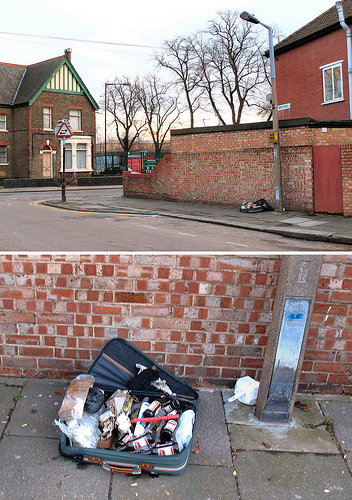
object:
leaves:
[93, 202, 126, 208]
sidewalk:
[43, 197, 352, 252]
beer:
[160, 410, 182, 445]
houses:
[0, 47, 170, 189]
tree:
[99, 76, 145, 171]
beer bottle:
[144, 397, 167, 427]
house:
[262, 0, 352, 120]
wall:
[123, 117, 352, 218]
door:
[56, 123, 73, 137]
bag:
[228, 376, 261, 405]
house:
[0, 47, 99, 188]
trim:
[43, 58, 86, 95]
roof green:
[66, 58, 99, 111]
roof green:
[29, 58, 65, 106]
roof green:
[43, 88, 84, 95]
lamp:
[254, 253, 322, 422]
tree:
[189, 11, 283, 125]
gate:
[313, 146, 343, 213]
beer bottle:
[141, 442, 180, 455]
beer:
[114, 433, 153, 452]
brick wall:
[123, 127, 352, 217]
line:
[143, 223, 156, 229]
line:
[179, 231, 197, 237]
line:
[228, 241, 248, 247]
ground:
[0, 185, 352, 251]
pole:
[62, 137, 66, 201]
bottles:
[115, 393, 195, 455]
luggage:
[58, 337, 197, 475]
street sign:
[56, 118, 73, 201]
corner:
[43, 195, 158, 215]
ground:
[0, 379, 352, 500]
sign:
[269, 132, 278, 143]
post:
[240, 10, 283, 212]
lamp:
[240, 11, 260, 24]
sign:
[55, 119, 73, 141]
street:
[0, 184, 123, 205]